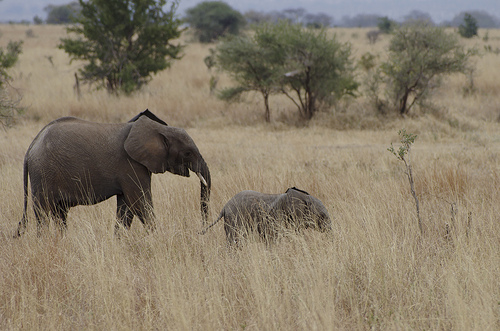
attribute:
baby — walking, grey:
[223, 185, 349, 239]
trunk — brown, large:
[196, 176, 216, 219]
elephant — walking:
[49, 122, 181, 195]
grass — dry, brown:
[365, 229, 439, 294]